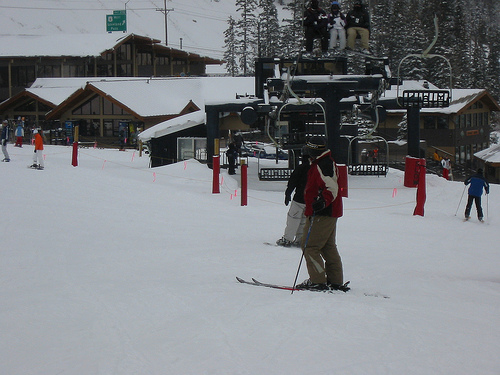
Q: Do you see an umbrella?
A: No, there are no umbrellas.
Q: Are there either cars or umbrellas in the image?
A: No, there are no umbrellas or cars.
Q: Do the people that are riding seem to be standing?
A: Yes, the people are standing.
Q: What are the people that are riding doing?
A: The people are standing.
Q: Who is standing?
A: The people are standing.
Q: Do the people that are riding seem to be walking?
A: No, the people are standing.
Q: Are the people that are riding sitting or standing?
A: The people are standing.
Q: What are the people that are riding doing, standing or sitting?
A: The people are standing.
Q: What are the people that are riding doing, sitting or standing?
A: The people are standing.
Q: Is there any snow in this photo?
A: Yes, there is snow.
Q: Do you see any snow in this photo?
A: Yes, there is snow.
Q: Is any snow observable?
A: Yes, there is snow.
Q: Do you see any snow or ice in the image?
A: Yes, there is snow.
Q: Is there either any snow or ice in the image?
A: Yes, there is snow.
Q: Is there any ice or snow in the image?
A: Yes, there is snow.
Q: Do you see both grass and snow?
A: No, there is snow but no grass.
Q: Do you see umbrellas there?
A: No, there are no umbrellas.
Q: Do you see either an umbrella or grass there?
A: No, there are no umbrellas or grass.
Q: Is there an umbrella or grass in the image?
A: No, there are no umbrellas or grass.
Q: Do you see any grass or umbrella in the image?
A: No, there are no umbrellas or grass.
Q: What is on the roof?
A: The snow is on the roof.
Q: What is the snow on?
A: The snow is on the roof.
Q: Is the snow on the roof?
A: Yes, the snow is on the roof.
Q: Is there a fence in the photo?
A: No, there are no fences.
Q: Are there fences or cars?
A: No, there are no fences or cars.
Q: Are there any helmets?
A: No, there are no helmets.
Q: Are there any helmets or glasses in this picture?
A: No, there are no helmets or glasses.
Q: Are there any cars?
A: No, there are no cars.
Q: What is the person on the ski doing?
A: The person is skiing.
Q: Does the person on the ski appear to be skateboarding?
A: No, the person is skiing.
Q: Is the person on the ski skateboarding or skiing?
A: The person is skiing.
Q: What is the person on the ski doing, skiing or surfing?
A: The person is skiing.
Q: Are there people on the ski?
A: Yes, there is a person on the ski.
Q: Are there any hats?
A: Yes, there is a hat.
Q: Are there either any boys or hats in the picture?
A: Yes, there is a hat.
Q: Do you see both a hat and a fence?
A: No, there is a hat but no fences.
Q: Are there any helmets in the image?
A: No, there are no helmets.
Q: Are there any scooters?
A: No, there are no scooters.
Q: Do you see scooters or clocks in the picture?
A: No, there are no scooters or clocks.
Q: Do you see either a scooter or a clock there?
A: No, there are no scooters or clocks.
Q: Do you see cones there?
A: No, there are no cones.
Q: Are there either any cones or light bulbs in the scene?
A: No, there are no cones or light bulbs.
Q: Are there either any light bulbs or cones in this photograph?
A: No, there are no cones or light bulbs.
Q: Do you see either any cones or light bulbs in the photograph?
A: No, there are no cones or light bulbs.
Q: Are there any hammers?
A: No, there are no hammers.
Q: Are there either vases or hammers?
A: No, there are no hammers or vases.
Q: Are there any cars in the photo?
A: No, there are no cars.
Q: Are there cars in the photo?
A: No, there are no cars.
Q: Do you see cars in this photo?
A: No, there are no cars.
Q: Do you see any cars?
A: No, there are no cars.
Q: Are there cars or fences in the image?
A: No, there are no cars or fences.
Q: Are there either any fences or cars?
A: No, there are no cars or fences.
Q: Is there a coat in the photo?
A: Yes, there is a coat.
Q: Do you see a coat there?
A: Yes, there is a coat.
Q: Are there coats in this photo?
A: Yes, there is a coat.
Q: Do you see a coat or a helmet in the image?
A: Yes, there is a coat.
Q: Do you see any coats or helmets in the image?
A: Yes, there is a coat.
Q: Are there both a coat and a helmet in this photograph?
A: No, there is a coat but no helmets.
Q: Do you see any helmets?
A: No, there are no helmets.